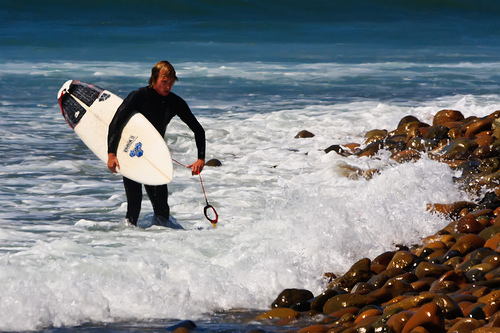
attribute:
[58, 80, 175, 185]
surfboard — white, mostly white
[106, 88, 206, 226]
suit — black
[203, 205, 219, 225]
handle — attached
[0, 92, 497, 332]
foam — white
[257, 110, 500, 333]
rocks — brown, wet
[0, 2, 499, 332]
sun — shining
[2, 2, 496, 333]
water — blue